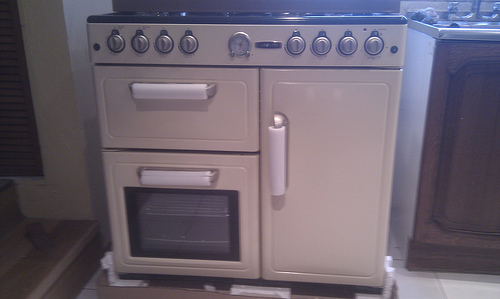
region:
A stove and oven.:
[84, 2, 409, 287]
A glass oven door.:
[122, 185, 240, 260]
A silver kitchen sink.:
[404, 2, 499, 37]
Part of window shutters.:
[3, 0, 45, 178]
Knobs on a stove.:
[105, 27, 384, 57]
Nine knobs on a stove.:
[104, 28, 384, 58]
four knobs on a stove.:
[104, 28, 199, 55]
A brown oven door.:
[90, 63, 261, 154]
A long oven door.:
[258, 65, 403, 289]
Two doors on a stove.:
[91, 61, 263, 280]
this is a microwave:
[101, 24, 411, 278]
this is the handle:
[261, 119, 293, 196]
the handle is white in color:
[262, 122, 294, 192]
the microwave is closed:
[119, 173, 240, 268]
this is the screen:
[140, 202, 235, 252]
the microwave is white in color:
[324, 115, 371, 202]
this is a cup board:
[455, 80, 488, 202]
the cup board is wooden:
[455, 104, 493, 188]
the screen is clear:
[158, 200, 230, 247]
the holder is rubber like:
[266, 126, 291, 183]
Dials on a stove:
[103, 28, 391, 57]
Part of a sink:
[408, 3, 498, 28]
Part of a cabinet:
[414, 33, 499, 281]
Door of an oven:
[104, 157, 263, 278]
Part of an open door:
[6, 2, 46, 184]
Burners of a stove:
[89, 2, 405, 27]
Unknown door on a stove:
[264, 80, 392, 280]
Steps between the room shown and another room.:
[2, 175, 95, 296]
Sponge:
[413, 6, 442, 27]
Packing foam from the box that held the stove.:
[96, 254, 149, 296]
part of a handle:
[251, 125, 304, 177]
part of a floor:
[421, 273, 447, 288]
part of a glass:
[171, 196, 221, 230]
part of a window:
[4, 108, 38, 159]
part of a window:
[51, 230, 80, 272]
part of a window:
[52, 138, 79, 193]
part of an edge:
[88, 147, 97, 191]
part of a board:
[445, 130, 490, 218]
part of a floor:
[20, 214, 51, 244]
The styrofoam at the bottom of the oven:
[98, 250, 397, 297]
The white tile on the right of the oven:
[388, 239, 499, 297]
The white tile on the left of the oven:
[74, 260, 109, 297]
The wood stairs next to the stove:
[0, 180, 104, 297]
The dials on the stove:
[101, 26, 398, 65]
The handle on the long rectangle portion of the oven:
[267, 107, 290, 200]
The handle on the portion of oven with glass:
[133, 163, 221, 193]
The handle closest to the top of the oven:
[123, 77, 224, 104]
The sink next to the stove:
[410, 2, 499, 38]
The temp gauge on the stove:
[226, 28, 252, 61]